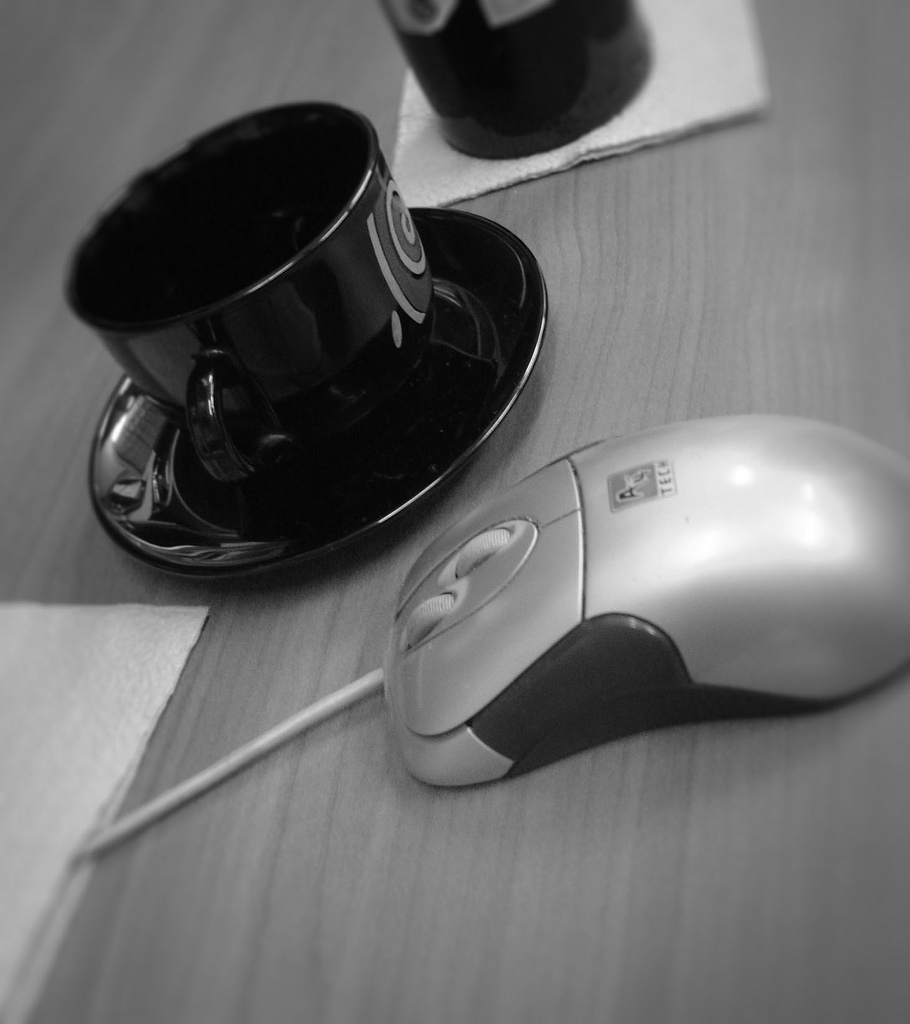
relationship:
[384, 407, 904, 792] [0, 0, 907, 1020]
computer mouse on table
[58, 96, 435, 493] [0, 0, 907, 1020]
cup on table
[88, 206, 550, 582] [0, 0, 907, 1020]
saucer on table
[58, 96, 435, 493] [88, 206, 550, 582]
cup on saucer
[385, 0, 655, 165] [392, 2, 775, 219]
object on a napkin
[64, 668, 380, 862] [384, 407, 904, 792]
wire connector for computer mouse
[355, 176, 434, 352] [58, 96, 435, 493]
design on cup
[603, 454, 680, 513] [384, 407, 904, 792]
brand name on computer mouse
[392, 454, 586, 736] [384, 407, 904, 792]
clicker on computer mouse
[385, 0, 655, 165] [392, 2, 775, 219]
object on napkin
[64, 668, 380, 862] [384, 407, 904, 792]
wire connector on computer mouse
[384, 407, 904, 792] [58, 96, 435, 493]
computer mouse next to cup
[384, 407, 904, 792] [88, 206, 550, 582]
computer mouse next to saucer